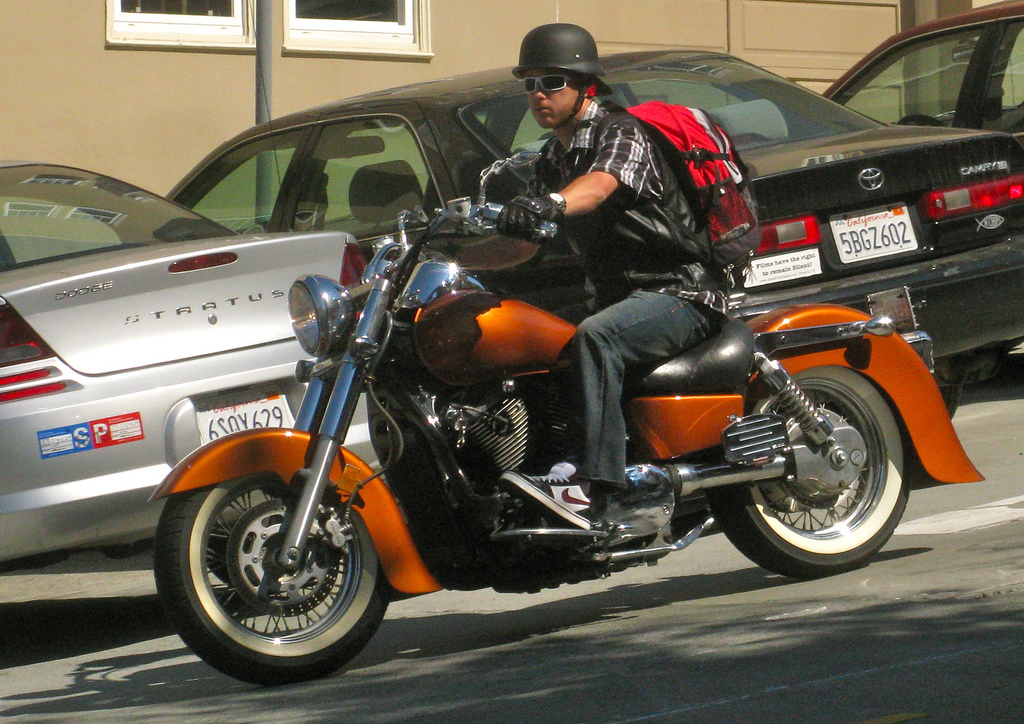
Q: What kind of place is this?
A: It is a street.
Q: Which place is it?
A: It is a street.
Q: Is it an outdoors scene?
A: Yes, it is outdoors.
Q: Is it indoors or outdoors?
A: It is outdoors.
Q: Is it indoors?
A: No, it is outdoors.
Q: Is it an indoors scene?
A: No, it is outdoors.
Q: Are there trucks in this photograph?
A: No, there are no trucks.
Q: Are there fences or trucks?
A: No, there are no trucks or fences.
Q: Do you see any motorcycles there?
A: Yes, there is a motorcycle.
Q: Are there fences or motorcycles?
A: Yes, there is a motorcycle.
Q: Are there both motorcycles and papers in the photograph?
A: No, there is a motorcycle but no papers.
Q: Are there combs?
A: No, there are no combs.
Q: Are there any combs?
A: No, there are no combs.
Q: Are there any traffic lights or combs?
A: No, there are no combs or traffic lights.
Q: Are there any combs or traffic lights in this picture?
A: No, there are no combs or traffic lights.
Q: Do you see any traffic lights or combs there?
A: No, there are no combs or traffic lights.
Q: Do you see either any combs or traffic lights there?
A: No, there are no combs or traffic lights.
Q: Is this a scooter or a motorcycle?
A: This is a motorcycle.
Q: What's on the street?
A: The motorbike is on the street.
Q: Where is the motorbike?
A: The motorbike is on the street.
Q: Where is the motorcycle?
A: The motorbike is on the street.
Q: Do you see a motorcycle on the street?
A: Yes, there is a motorcycle on the street.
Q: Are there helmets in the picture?
A: Yes, there is a helmet.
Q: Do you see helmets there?
A: Yes, there is a helmet.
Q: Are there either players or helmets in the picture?
A: Yes, there is a helmet.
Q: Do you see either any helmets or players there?
A: Yes, there is a helmet.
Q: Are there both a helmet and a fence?
A: No, there is a helmet but no fences.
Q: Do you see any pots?
A: No, there are no pots.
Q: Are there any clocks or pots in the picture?
A: No, there are no pots or clocks.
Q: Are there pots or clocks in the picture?
A: No, there are no pots or clocks.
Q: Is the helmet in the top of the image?
A: Yes, the helmet is in the top of the image.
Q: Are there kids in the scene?
A: No, there are no kids.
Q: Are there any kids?
A: No, there are no kids.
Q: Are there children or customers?
A: No, there are no children or customers.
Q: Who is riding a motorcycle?
A: The man is riding a motorcycle.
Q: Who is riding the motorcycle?
A: The man is riding a motorcycle.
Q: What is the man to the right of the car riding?
A: The man is riding a motorcycle.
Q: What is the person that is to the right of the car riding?
A: The man is riding a motorcycle.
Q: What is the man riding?
A: The man is riding a motorcycle.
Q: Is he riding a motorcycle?
A: Yes, the man is riding a motorcycle.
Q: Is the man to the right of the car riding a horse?
A: No, the man is riding a motorcycle.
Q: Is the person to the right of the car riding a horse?
A: No, the man is riding a motorcycle.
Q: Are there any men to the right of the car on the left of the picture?
A: Yes, there is a man to the right of the car.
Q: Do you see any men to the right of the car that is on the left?
A: Yes, there is a man to the right of the car.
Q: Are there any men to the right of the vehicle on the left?
A: Yes, there is a man to the right of the car.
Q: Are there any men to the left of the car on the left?
A: No, the man is to the right of the car.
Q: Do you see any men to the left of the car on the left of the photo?
A: No, the man is to the right of the car.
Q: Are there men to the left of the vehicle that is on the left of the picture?
A: No, the man is to the right of the car.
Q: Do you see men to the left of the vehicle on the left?
A: No, the man is to the right of the car.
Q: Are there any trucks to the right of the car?
A: No, there is a man to the right of the car.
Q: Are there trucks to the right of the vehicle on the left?
A: No, there is a man to the right of the car.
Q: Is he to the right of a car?
A: Yes, the man is to the right of a car.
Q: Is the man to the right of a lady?
A: No, the man is to the right of a car.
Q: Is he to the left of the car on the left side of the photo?
A: No, the man is to the right of the car.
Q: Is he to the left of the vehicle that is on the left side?
A: No, the man is to the right of the car.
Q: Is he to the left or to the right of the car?
A: The man is to the right of the car.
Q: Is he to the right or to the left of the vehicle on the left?
A: The man is to the right of the car.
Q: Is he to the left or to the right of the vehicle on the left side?
A: The man is to the right of the car.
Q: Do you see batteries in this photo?
A: No, there are no batteries.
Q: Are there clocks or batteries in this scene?
A: No, there are no batteries or clocks.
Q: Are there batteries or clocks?
A: No, there are no batteries or clocks.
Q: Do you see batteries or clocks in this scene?
A: No, there are no batteries or clocks.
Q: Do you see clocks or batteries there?
A: No, there are no batteries or clocks.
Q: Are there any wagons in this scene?
A: No, there are no wagons.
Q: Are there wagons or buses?
A: No, there are no wagons or buses.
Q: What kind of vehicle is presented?
A: The vehicle is a car.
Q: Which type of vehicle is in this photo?
A: The vehicle is a car.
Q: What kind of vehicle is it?
A: The vehicle is a car.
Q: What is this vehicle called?
A: This is a car.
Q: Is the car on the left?
A: Yes, the car is on the left of the image.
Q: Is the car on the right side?
A: No, the car is on the left of the image.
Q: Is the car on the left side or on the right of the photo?
A: The car is on the left of the image.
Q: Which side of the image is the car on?
A: The car is on the left of the image.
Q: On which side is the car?
A: The car is on the left of the image.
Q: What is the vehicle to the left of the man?
A: The vehicle is a car.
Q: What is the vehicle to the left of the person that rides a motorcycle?
A: The vehicle is a car.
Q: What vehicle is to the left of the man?
A: The vehicle is a car.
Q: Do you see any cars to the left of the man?
A: Yes, there is a car to the left of the man.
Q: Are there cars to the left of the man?
A: Yes, there is a car to the left of the man.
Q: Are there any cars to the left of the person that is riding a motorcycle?
A: Yes, there is a car to the left of the man.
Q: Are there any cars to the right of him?
A: No, the car is to the left of the man.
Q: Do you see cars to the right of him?
A: No, the car is to the left of the man.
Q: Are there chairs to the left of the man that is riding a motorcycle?
A: No, there is a car to the left of the man.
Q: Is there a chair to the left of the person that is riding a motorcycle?
A: No, there is a car to the left of the man.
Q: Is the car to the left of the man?
A: Yes, the car is to the left of the man.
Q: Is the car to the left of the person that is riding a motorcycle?
A: Yes, the car is to the left of the man.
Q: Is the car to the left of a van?
A: No, the car is to the left of the man.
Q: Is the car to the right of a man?
A: No, the car is to the left of a man.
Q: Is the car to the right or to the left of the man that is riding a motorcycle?
A: The car is to the left of the man.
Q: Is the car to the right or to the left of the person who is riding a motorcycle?
A: The car is to the left of the man.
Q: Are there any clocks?
A: No, there are no clocks.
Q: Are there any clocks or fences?
A: No, there are no clocks or fences.